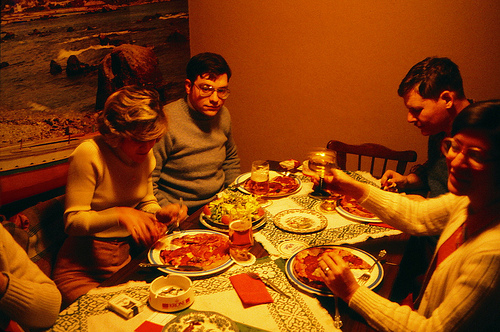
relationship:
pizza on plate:
[162, 235, 230, 274] [147, 228, 240, 277]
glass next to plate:
[226, 206, 254, 257] [147, 228, 240, 277]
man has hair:
[150, 50, 243, 213] [187, 51, 229, 81]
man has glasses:
[150, 50, 243, 213] [190, 80, 231, 99]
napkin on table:
[229, 271, 267, 306] [27, 158, 408, 332]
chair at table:
[323, 136, 414, 179] [27, 158, 408, 332]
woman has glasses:
[317, 102, 495, 328] [439, 134, 490, 172]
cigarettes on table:
[107, 292, 141, 318] [27, 158, 408, 332]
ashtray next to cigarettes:
[146, 277, 195, 308] [107, 292, 141, 318]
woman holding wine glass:
[317, 102, 495, 328] [306, 149, 339, 199]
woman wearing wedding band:
[317, 102, 495, 328] [324, 265, 333, 274]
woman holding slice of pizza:
[317, 102, 495, 328] [302, 252, 343, 279]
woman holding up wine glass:
[317, 102, 495, 328] [306, 149, 339, 199]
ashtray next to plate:
[146, 277, 195, 308] [147, 228, 240, 277]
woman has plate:
[61, 86, 178, 292] [147, 228, 240, 277]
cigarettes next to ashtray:
[107, 292, 141, 318] [146, 277, 195, 308]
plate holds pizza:
[147, 228, 240, 277] [162, 235, 230, 274]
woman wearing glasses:
[317, 102, 495, 328] [439, 134, 490, 172]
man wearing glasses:
[150, 50, 243, 213] [190, 80, 231, 99]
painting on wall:
[1, 2, 189, 169] [1, 2, 195, 214]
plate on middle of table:
[272, 208, 329, 233] [27, 158, 408, 332]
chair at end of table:
[323, 136, 414, 179] [27, 158, 408, 332]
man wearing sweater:
[150, 50, 243, 213] [155, 98, 240, 203]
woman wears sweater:
[61, 86, 178, 292] [63, 137, 162, 241]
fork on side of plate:
[357, 245, 388, 286] [288, 243, 385, 300]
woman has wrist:
[317, 102, 495, 328] [343, 280, 368, 308]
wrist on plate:
[343, 280, 368, 308] [288, 243, 385, 300]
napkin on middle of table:
[229, 271, 267, 306] [27, 158, 408, 332]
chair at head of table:
[323, 136, 414, 179] [27, 158, 408, 332]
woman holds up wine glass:
[317, 102, 495, 328] [306, 149, 339, 199]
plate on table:
[147, 228, 240, 277] [27, 158, 408, 332]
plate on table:
[288, 243, 385, 300] [27, 158, 408, 332]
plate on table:
[234, 166, 301, 197] [27, 158, 408, 332]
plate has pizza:
[234, 166, 301, 197] [247, 175, 297, 196]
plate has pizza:
[336, 194, 380, 225] [340, 195, 375, 222]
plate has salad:
[200, 193, 268, 236] [207, 190, 265, 224]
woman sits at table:
[317, 102, 495, 328] [27, 158, 408, 332]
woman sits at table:
[61, 86, 178, 292] [27, 158, 408, 332]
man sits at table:
[150, 50, 243, 213] [27, 158, 408, 332]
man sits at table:
[383, 58, 466, 203] [27, 158, 408, 332]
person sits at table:
[0, 220, 62, 317] [27, 158, 408, 332]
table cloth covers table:
[55, 259, 335, 331] [27, 158, 408, 332]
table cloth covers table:
[223, 158, 415, 255] [27, 158, 408, 332]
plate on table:
[162, 313, 229, 332] [27, 158, 408, 332]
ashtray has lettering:
[146, 277, 195, 308] [160, 297, 195, 310]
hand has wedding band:
[316, 249, 359, 298] [324, 265, 333, 274]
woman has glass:
[61, 86, 178, 292] [226, 206, 254, 257]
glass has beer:
[226, 206, 254, 257] [228, 222, 259, 253]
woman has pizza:
[317, 102, 495, 328] [296, 247, 357, 287]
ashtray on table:
[146, 277, 195, 308] [27, 158, 408, 332]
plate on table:
[272, 208, 329, 233] [27, 158, 408, 332]